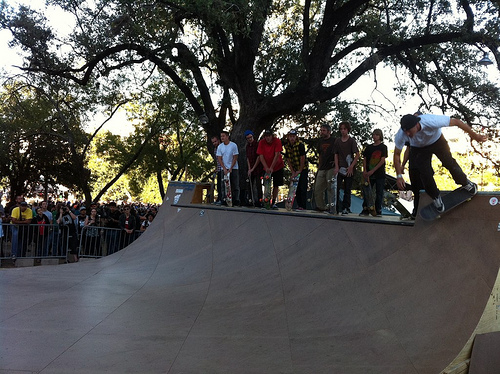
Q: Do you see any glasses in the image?
A: No, there are no glasses.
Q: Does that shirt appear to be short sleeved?
A: Yes, the shirt is short sleeved.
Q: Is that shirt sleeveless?
A: No, the shirt is short sleeved.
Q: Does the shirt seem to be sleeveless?
A: No, the shirt is short sleeved.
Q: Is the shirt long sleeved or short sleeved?
A: The shirt is short sleeved.